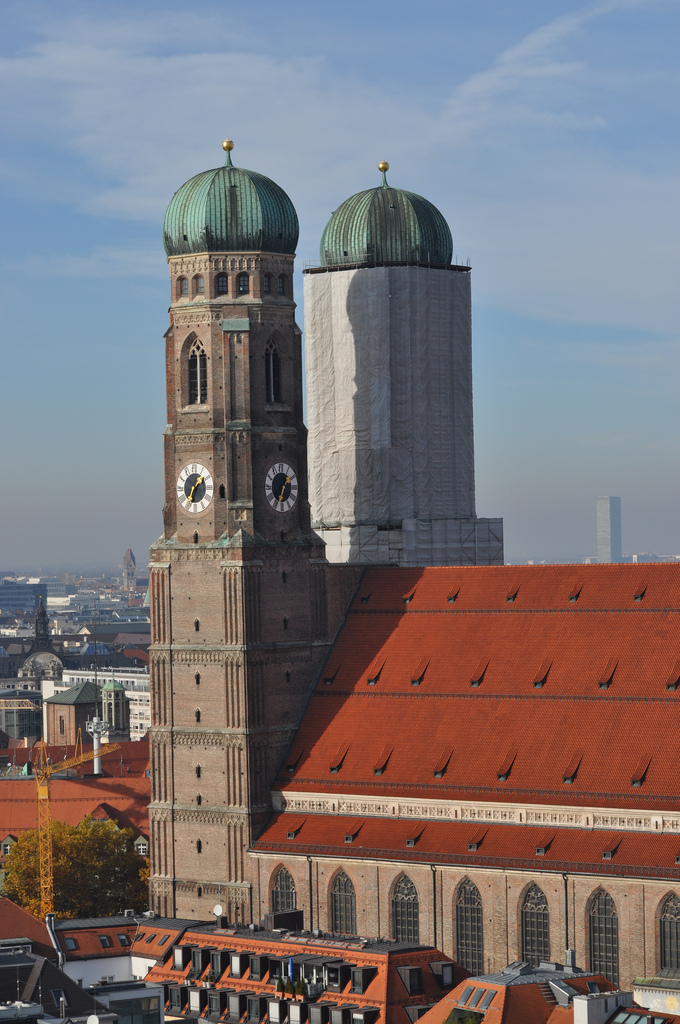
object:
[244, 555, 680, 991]
building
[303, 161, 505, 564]
building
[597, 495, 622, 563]
building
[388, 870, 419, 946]
window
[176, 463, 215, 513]
clock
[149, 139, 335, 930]
building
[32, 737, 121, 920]
crane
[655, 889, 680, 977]
window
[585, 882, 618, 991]
window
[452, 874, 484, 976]
window